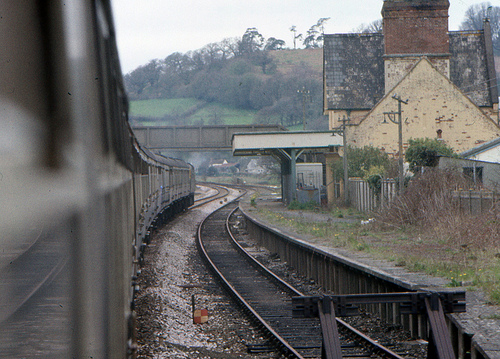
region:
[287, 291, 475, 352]
A barricade is set up on the tracks.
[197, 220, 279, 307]
Windy railroad tracks.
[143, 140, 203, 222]
A line of train cars.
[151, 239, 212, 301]
Rocks between the tracks.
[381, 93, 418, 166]
Old telephone poles.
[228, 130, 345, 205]
A cover for passengers.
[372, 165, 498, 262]
Dried out brush.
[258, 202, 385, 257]
Dandelions line the track.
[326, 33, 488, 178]
An old train station.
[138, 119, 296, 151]
A bridge in the back ground.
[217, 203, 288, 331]
the empty train tracks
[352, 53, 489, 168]
the building is tan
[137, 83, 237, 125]
hill in the background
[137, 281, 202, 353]
stones on the ground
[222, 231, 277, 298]
wood on the tracks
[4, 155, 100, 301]
blurry part of station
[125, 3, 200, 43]
the sky is hazy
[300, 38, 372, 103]
roof of the building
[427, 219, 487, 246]
the bushes are dead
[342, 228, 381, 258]
sparse patches of dirt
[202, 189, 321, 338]
track on the ground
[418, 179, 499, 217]
fence near a building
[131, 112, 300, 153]
area connecting overhead areas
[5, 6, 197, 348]
train on the track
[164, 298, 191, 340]
rocks on the ground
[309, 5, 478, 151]
building near the tracks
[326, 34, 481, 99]
roof that slants to an angle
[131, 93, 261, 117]
terrain that is elevated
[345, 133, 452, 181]
trees near a fence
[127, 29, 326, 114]
trees in the distance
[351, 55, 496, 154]
top of house is triangular shaped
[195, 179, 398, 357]
curvy railroad tracks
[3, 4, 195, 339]
a train is on the tracks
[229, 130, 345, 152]
a white awning over a patio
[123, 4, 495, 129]
green trees growing on the hillside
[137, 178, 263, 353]
rocks are in between the two railroad tracks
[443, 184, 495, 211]
fence around the side of a house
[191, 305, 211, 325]
round red and yellow sign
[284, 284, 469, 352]
black wooden barrier at the end of the tracks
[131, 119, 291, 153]
metal bridge above the tracks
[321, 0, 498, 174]
An old brick building.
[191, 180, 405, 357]
A set of train tracks.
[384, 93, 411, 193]
A brown power pole.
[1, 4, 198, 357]
A line of train cars.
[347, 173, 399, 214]
A brown wooden fence.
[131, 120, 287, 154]
A gray cement bridge.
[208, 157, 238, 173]
A distant white house.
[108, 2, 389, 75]
An overcast gray sky.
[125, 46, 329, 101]
A tree covered hill.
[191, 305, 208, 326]
Red and white sign.